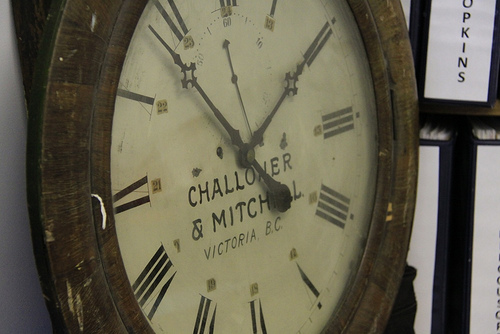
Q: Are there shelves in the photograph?
A: No, there are no shelves.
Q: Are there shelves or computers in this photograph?
A: No, there are no shelves or computers.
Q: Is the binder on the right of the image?
A: Yes, the binder is on the right of the image.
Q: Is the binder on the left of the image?
A: No, the binder is on the right of the image.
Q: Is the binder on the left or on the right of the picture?
A: The binder is on the right of the image.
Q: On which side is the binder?
A: The binder is on the right of the image.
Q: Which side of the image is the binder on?
A: The binder is on the right of the image.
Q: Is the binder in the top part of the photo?
A: Yes, the binder is in the top of the image.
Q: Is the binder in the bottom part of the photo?
A: No, the binder is in the top of the image.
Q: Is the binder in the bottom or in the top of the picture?
A: The binder is in the top of the image.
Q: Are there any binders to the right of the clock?
A: Yes, there is a binder to the right of the clock.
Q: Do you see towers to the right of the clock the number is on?
A: No, there is a binder to the right of the clock.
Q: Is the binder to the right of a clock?
A: Yes, the binder is to the right of a clock.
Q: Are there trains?
A: No, there are no trains.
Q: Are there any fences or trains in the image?
A: No, there are no trains or fences.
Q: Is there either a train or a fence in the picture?
A: No, there are no trains or fences.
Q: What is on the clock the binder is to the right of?
A: The number is on the clock.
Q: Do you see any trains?
A: No, there are no trains.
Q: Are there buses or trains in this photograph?
A: No, there are no trains or buses.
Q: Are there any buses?
A: No, there are no buses.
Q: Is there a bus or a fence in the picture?
A: No, there are no buses or fences.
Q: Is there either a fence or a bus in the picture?
A: No, there are no buses or fences.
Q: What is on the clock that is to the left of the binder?
A: The number is on the clock.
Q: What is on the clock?
A: The number is on the clock.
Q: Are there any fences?
A: No, there are no fences.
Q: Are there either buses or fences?
A: No, there are no fences or buses.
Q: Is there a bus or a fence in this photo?
A: No, there are no fences or buses.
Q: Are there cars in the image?
A: No, there are no cars.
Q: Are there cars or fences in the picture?
A: No, there are no cars or fences.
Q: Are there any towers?
A: No, there are no towers.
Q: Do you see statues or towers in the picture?
A: No, there are no towers or statues.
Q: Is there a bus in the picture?
A: No, there are no buses.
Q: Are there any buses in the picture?
A: No, there are no buses.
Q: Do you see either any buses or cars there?
A: No, there are no buses or cars.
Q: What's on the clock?
A: The number is on the clock.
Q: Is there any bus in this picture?
A: No, there are no buses.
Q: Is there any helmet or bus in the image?
A: No, there are no buses or helmets.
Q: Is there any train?
A: No, there are no trains.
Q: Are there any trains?
A: No, there are no trains.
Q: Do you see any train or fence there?
A: No, there are no trains or fences.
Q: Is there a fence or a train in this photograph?
A: No, there are no trains or fences.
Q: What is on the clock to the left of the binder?
A: The number is on the clock.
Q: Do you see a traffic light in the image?
A: No, there are no traffic lights.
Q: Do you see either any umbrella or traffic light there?
A: No, there are no traffic lights or umbrellas.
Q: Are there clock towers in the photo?
A: No, there are no clock towers.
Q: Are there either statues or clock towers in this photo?
A: No, there are no clock towers or statues.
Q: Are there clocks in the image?
A: Yes, there is a clock.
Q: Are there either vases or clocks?
A: Yes, there is a clock.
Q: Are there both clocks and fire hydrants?
A: No, there is a clock but no fire hydrants.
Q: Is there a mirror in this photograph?
A: No, there are no mirrors.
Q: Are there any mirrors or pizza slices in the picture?
A: No, there are no mirrors or pizza slices.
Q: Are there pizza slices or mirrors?
A: No, there are no mirrors or pizza slices.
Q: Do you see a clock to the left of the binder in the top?
A: Yes, there is a clock to the left of the binder.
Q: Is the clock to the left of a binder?
A: Yes, the clock is to the left of a binder.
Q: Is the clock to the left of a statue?
A: No, the clock is to the left of a binder.